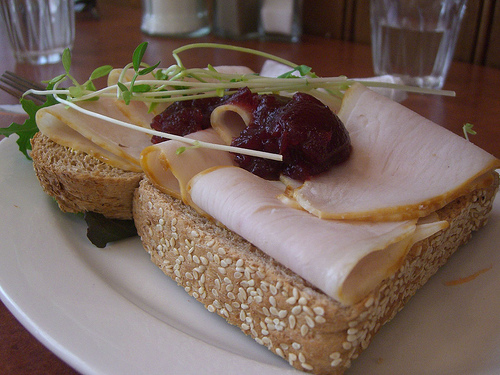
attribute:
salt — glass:
[138, 0, 210, 40]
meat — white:
[292, 82, 494, 216]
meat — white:
[62, 38, 497, 294]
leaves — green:
[15, 44, 198, 155]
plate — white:
[16, 245, 178, 364]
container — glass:
[137, 0, 212, 40]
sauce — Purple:
[271, 100, 319, 176]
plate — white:
[0, 88, 497, 373]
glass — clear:
[357, 2, 488, 107]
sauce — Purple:
[149, 88, 348, 184]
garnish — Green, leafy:
[8, 39, 456, 166]